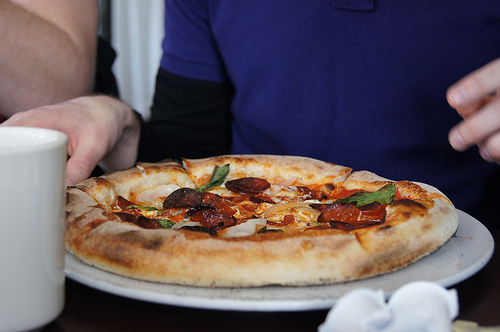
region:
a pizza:
[68, 140, 449, 291]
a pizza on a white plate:
[57, 153, 492, 313]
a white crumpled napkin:
[323, 273, 484, 326]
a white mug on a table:
[1, 111, 69, 327]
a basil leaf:
[350, 180, 400, 206]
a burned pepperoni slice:
[162, 183, 202, 211]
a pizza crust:
[130, 230, 270, 286]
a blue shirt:
[220, 1, 495, 151]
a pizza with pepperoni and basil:
[92, 136, 443, 281]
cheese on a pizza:
[270, 195, 313, 220]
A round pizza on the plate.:
[68, 145, 433, 287]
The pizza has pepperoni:
[320, 187, 378, 227]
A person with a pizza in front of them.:
[99, 6, 498, 259]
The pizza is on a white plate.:
[78, 123, 458, 330]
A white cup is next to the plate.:
[20, 118, 90, 330]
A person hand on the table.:
[31, 53, 149, 167]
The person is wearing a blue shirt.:
[226, 31, 438, 153]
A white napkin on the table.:
[326, 286, 479, 326]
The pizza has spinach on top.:
[337, 180, 387, 210]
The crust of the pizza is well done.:
[122, 216, 219, 274]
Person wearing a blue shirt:
[155, 1, 496, 168]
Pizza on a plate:
[61, 167, 475, 310]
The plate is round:
[76, 171, 483, 308]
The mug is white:
[5, 118, 112, 330]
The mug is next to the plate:
[6, 120, 461, 327]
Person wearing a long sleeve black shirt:
[142, 3, 496, 193]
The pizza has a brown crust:
[78, 160, 437, 279]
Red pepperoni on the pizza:
[138, 167, 390, 244]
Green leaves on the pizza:
[201, 156, 403, 213]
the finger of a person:
[441, 57, 499, 111]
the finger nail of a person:
[447, 81, 470, 105]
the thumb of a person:
[61, 130, 108, 190]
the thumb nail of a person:
[62, 170, 82, 194]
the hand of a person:
[0, 83, 137, 181]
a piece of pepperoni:
[222, 169, 274, 198]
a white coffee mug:
[0, 122, 72, 329]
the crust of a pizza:
[180, 150, 352, 185]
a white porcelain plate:
[60, 195, 495, 316]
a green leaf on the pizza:
[193, 153, 236, 195]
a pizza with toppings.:
[57, 144, 459, 277]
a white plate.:
[441, 237, 487, 294]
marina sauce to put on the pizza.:
[303, 280, 475, 330]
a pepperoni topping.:
[168, 184, 387, 234]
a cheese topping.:
[271, 184, 314, 223]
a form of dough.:
[113, 224, 371, 289]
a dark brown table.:
[56, 293, 177, 330]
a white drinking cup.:
[0, 123, 89, 330]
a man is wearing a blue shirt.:
[255, 50, 380, 118]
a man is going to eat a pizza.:
[56, 0, 496, 329]